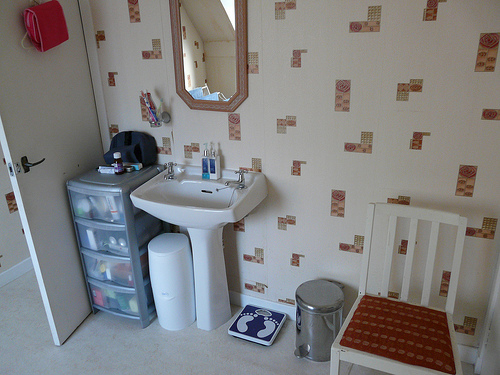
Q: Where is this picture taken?
A: A bathroom.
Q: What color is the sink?
A: White.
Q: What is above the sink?
A: A mirror.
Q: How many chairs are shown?
A: One.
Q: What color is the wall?
A: Brown and white.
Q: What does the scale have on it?
A: Footprints.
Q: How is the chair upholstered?
A: In fabric.